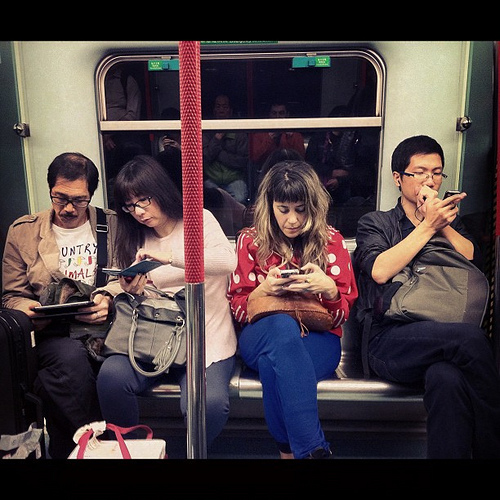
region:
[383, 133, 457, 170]
Person has dark hair.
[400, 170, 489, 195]
Glasses on person's face.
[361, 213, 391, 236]
Person wearing black jacket.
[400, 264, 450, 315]
Person holding bag in lap.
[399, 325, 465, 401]
Person wearing dark pants.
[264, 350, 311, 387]
Person wearing blue pants.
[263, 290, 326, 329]
Person holding brown bag in lap.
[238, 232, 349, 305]
Person wearing red and white jacket.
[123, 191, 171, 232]
Glasses on woman's face.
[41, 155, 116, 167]
Man has short dark hair.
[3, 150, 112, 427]
A man holding a tablet device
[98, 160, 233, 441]
A woman in eyeglasses holding a book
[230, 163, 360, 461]
A woman in red holds a cellular phone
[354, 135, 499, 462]
A man in glasses on his phone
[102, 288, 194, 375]
A gray handbag in a woman's lap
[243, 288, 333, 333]
A brown handbag in a woman's lap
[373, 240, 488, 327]
A gray backpack in a man's lap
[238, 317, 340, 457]
A woman's blue pants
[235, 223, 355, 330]
A woman's polka dot shirt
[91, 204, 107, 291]
The strap of a man's bag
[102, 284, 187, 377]
black and grey handbag with tassels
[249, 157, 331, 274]
long hair parted in the middle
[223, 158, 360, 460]
woman sitting with her legs crossed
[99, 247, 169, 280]
hand turning the pages of a small book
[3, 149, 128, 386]
man looking at a tablet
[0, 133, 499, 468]
four people sitting side by side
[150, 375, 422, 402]
metallic bench seat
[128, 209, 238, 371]
knitted long sleeved sweater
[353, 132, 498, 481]
man holding his hand up to his mouth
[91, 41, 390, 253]
tinted window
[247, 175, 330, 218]
hair of the woman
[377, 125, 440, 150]
hair of the man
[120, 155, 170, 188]
hair of the woman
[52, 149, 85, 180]
hair of the man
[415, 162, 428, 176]
eye of the man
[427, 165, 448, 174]
eye of the man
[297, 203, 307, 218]
eye of the woman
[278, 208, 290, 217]
eye of the woman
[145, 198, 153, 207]
eye of the woman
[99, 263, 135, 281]
book in the hand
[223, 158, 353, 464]
woman sitting on train wearing blue jeans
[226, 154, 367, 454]
woman with long blond hair wearing red shirt with white polka dots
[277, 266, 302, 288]
woman holding phone in both hands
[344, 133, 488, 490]
Asian man sitting on train in blue jeans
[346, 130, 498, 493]
Asian man holding cell phone and wearing glasses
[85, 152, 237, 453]
long hiared Asian woman sitting on train reading brochure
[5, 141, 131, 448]
Balding Asian man sitting next to Asian woman reading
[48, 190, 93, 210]
balding Asian man wearing glasses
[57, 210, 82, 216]
balding Asian man with dark mustache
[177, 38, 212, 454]
silver pole with red rubber grip for passengers to hold